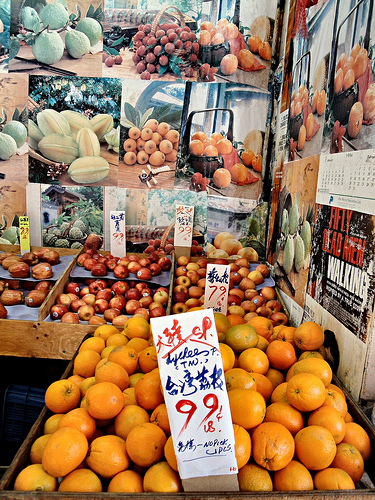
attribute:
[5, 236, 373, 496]
crates — wooden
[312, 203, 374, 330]
poster — black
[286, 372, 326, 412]
orange — ripe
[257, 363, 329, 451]
oranges — orange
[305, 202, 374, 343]
sign — hanging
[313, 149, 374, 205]
white/black print — black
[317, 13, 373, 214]
calendar — white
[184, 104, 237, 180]
basket — dark wicker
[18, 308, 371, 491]
oranges — orange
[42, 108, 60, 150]
starfruit — pale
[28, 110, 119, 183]
star fruit — pale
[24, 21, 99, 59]
pears — green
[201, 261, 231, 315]
sign — blue, white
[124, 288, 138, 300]
apples — fruit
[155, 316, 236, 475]
writing — red, blue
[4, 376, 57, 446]
container — blue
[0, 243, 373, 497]
stand — wooden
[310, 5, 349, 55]
wall — white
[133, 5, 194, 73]
basket — wicker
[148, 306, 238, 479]
sign — white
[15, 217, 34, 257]
sign — bright yellow